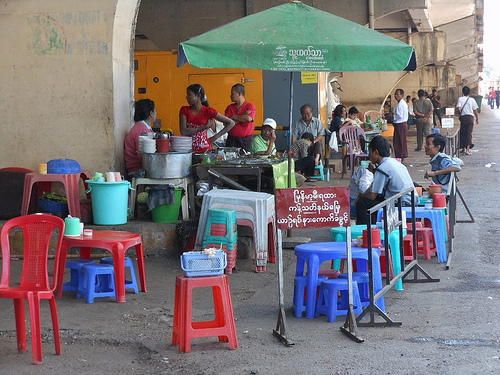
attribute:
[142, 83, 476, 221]
people — clustered, open air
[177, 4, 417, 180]
umbrella — green, a shade for sun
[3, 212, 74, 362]
chair — empty, red, plastic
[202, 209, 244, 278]
stools — within railing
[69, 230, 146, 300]
tables — within railing, red, plastic, small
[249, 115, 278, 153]
man — seated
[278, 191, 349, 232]
writing — elevated, curved, white, red, for restaurant, foreign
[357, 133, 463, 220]
men — facing building, seated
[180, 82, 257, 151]
woman and man — face same direction, looking left, wearing shirts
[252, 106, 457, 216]
people — seated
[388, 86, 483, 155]
people — walking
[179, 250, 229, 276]
basket — blue, baby blue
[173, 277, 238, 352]
stool — red, plastic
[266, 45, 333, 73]
writing — white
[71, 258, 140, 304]
chair — small, blue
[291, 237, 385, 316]
table — small, blue, plastic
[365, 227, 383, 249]
bucket — small, red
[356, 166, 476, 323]
rails — for guarding, metal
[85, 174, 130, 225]
bucket — green, blue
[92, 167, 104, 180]
rags — green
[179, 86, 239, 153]
woman — standing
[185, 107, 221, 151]
shirt — red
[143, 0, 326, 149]
wall — yellow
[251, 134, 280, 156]
shirt — green